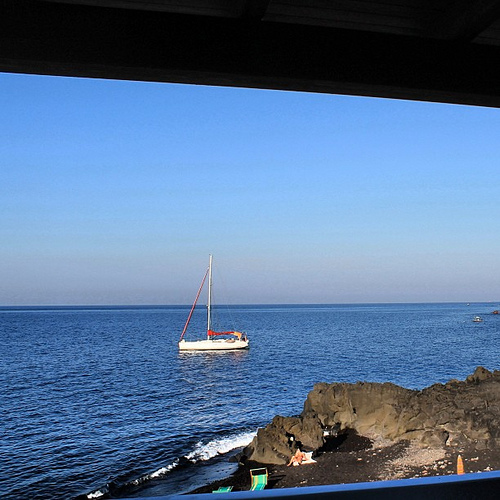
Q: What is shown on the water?
A: Boat.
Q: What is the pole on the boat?
A: Mast.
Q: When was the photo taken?
A: Daytime.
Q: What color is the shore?
A: Black.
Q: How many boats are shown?
A: One.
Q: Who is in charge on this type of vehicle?
A: Captain.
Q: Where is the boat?
A: In the ocean.